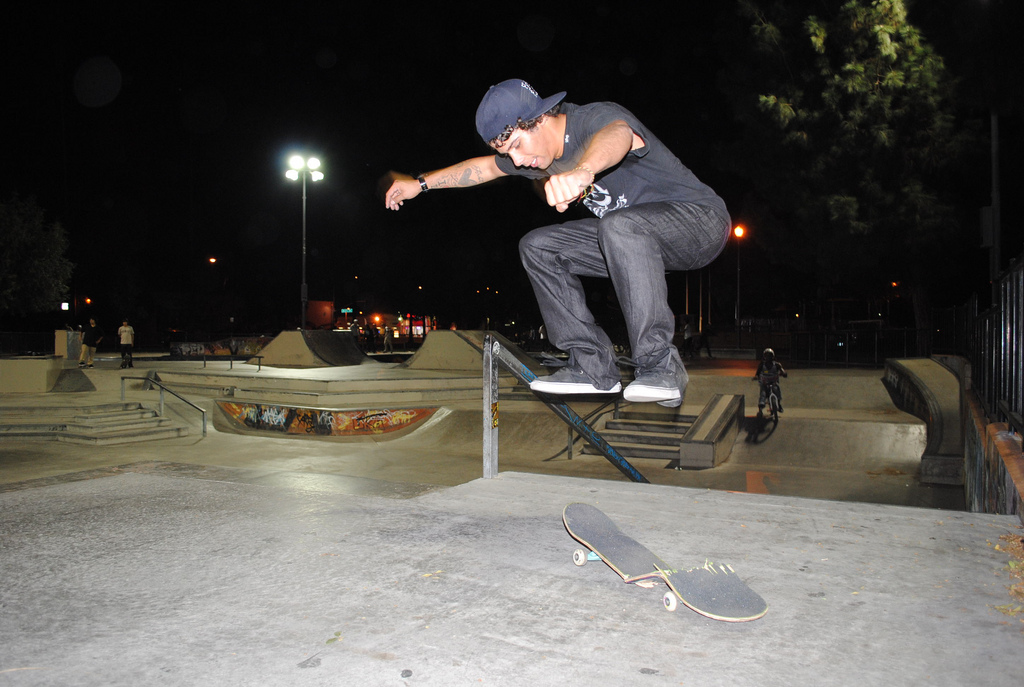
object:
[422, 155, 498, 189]
forearm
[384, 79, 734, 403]
man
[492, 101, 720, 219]
shirt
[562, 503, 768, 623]
skateboard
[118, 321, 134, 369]
guys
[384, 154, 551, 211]
arm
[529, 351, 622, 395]
shoe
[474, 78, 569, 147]
hat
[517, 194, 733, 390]
pants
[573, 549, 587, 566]
wheel